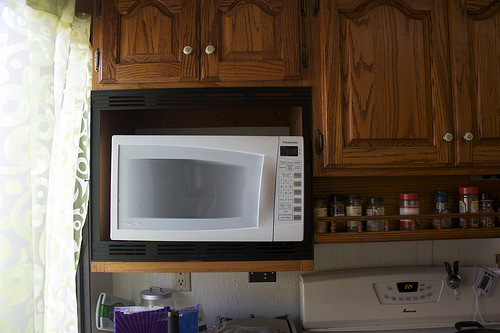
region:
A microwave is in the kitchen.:
[107, 131, 303, 241]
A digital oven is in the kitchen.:
[295, 260, 495, 327]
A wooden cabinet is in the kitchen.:
[305, 0, 495, 177]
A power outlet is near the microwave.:
[170, 272, 190, 292]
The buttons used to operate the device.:
[275, 170, 301, 221]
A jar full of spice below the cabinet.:
[396, 190, 421, 234]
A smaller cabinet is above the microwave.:
[90, 0, 317, 92]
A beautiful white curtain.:
[0, 1, 92, 331]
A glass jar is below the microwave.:
[137, 284, 176, 311]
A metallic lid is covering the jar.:
[138, 283, 175, 301]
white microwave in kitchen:
[122, 124, 299, 251]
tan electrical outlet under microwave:
[162, 273, 212, 292]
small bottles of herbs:
[321, 162, 491, 224]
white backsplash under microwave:
[214, 278, 259, 313]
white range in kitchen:
[300, 278, 488, 330]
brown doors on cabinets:
[90, 0, 310, 103]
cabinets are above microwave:
[102, 5, 289, 87]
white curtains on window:
[0, 32, 82, 277]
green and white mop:
[88, 287, 134, 329]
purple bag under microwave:
[112, 296, 161, 331]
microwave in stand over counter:
[106, 123, 308, 250]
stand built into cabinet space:
[88, 93, 320, 277]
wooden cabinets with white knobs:
[90, 3, 499, 178]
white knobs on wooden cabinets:
[181, 45, 476, 142]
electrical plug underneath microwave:
[171, 268, 192, 294]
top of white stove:
[296, 269, 498, 331]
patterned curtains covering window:
[0, 0, 96, 332]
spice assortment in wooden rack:
[311, 177, 498, 244]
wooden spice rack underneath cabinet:
[308, 213, 499, 244]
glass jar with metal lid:
[140, 283, 175, 311]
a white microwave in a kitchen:
[109, 132, 309, 244]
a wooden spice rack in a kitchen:
[314, 173, 499, 241]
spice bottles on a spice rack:
[316, 188, 497, 232]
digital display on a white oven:
[398, 280, 419, 293]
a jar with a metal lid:
[138, 283, 173, 307]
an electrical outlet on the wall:
[170, 272, 192, 292]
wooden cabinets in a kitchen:
[88, 1, 499, 173]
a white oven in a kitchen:
[298, 266, 498, 331]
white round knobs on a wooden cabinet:
[443, 132, 472, 142]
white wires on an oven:
[471, 263, 498, 325]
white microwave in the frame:
[109, 133, 306, 243]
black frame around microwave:
[88, 89, 318, 260]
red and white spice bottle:
[394, 187, 420, 229]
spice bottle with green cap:
[431, 188, 452, 226]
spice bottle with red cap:
[456, 183, 478, 224]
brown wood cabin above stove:
[309, 1, 456, 173]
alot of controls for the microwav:
[271, 137, 306, 227]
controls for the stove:
[370, 272, 448, 312]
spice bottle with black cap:
[326, 192, 343, 234]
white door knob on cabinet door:
[180, 40, 195, 63]